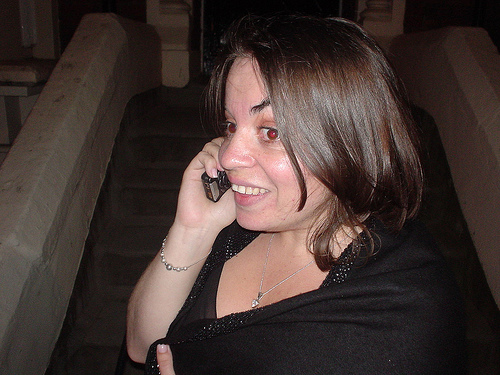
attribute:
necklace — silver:
[243, 231, 335, 310]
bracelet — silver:
[155, 237, 216, 276]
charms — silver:
[160, 242, 187, 275]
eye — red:
[264, 130, 278, 139]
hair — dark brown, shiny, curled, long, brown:
[205, 13, 424, 272]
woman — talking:
[126, 15, 464, 375]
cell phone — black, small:
[196, 159, 237, 205]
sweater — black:
[115, 219, 462, 375]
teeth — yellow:
[226, 184, 269, 197]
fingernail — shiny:
[156, 344, 169, 353]